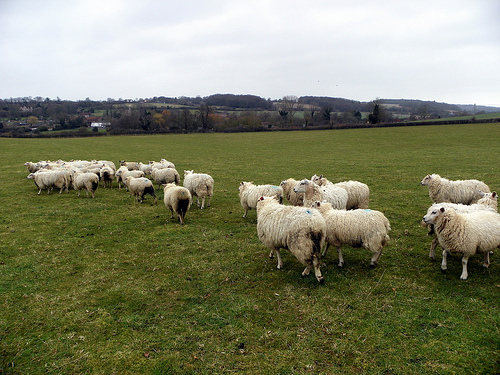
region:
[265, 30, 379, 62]
the sky is cloudy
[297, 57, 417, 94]
the sky is cloudy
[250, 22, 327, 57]
the sky is cloudy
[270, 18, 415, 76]
the sky is cloudy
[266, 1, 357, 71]
the sky is cloudy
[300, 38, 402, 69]
the sky is cloudy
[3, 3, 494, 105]
a hazy grey sky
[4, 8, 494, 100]
a cloudy sky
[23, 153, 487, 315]
a herd of sheep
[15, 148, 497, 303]
white hairy sheep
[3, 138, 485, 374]
green grassy field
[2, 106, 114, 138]
homes in the distance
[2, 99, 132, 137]
buildings in the distance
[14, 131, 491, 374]
sheep walking on a field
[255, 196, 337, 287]
a sheep with a blue spot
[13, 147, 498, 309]
a herd of sheep with blue marks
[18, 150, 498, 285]
sheep in a field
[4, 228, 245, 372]
green grass of a field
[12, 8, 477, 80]
cloudy sky in the distance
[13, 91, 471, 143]
view of the countryside in the background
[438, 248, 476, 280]
front two legs of a sheep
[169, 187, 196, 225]
backside of a sheep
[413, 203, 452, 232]
face of a sheep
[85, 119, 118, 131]
building in the background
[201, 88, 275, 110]
trees on a hill in the background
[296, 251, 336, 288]
back two legs of a sheep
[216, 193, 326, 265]
white animal on the ground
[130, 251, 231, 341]
green grass next to animals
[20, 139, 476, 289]
group of animals in the field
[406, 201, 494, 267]
animal facing the left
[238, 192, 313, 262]
white fur on animal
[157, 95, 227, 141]
trees far from the animals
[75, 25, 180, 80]
blue sky above land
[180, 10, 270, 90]
white clouds in the sky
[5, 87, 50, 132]
structures on a hill and trees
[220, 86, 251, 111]
green trees in the background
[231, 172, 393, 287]
a medium sized herd of sheep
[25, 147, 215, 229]
a larger herd of sheed in the lead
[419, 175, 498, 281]
a smaller herd of sheep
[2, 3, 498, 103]
the bright sky above everything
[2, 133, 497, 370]
a big field of grass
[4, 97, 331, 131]
a group of treees next to the field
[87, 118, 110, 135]
a white house in the background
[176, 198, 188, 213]
some black fur on the sheep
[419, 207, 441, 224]
the happy looking sheep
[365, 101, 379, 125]
a tall tree in the background